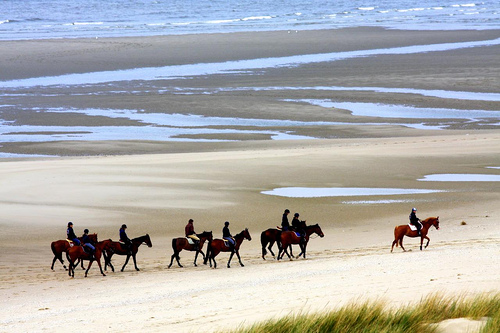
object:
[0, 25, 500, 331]
sand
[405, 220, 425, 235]
covering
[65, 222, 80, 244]
person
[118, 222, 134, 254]
person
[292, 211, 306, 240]
person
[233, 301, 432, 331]
grass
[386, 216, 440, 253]
horses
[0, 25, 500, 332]
beach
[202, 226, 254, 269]
horse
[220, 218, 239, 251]
person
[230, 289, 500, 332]
grass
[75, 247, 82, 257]
fur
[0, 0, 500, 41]
ocean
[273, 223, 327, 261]
horse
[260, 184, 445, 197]
water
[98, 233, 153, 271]
horse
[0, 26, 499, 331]
ground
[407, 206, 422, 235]
people